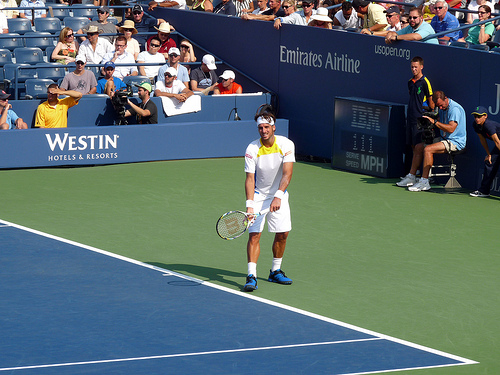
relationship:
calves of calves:
[246, 229, 262, 265] [244, 103, 293, 291]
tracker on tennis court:
[320, 75, 409, 180] [2, 155, 497, 371]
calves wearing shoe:
[244, 103, 293, 291] [229, 263, 304, 298]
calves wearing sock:
[244, 103, 293, 291] [246, 259, 256, 276]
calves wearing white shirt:
[244, 103, 293, 291] [243, 132, 294, 197]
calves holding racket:
[244, 103, 293, 291] [216, 207, 269, 241]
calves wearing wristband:
[244, 103, 293, 291] [268, 187, 295, 204]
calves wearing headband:
[244, 103, 293, 291] [253, 115, 274, 125]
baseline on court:
[0, 215, 482, 373] [16, 214, 473, 374]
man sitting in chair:
[423, 80, 474, 171] [435, 144, 465, 199]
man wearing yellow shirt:
[29, 83, 79, 128] [32, 96, 78, 130]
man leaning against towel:
[153, 69, 191, 99] [159, 89, 203, 116]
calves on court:
[244, 103, 293, 291] [2, 167, 497, 371]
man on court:
[393, 91, 470, 192] [2, 167, 497, 371]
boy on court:
[469, 106, 499, 198] [2, 167, 497, 371]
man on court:
[33, 83, 84, 128] [2, 167, 497, 371]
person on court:
[125, 82, 165, 129] [2, 167, 497, 371]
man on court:
[152, 65, 193, 100] [2, 167, 497, 371]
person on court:
[161, 44, 226, 97] [2, 167, 497, 371]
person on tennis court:
[404, 57, 434, 174] [2, 155, 497, 371]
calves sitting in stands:
[244, 103, 293, 291] [13, 7, 246, 153]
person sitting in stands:
[59, 53, 96, 98] [2, 0, 499, 167]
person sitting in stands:
[48, 25, 78, 65] [2, 0, 499, 167]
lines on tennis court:
[65, 247, 467, 365] [2, 155, 497, 371]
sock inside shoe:
[245, 261, 258, 278] [241, 273, 260, 292]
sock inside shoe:
[269, 257, 283, 270] [269, 266, 293, 284]